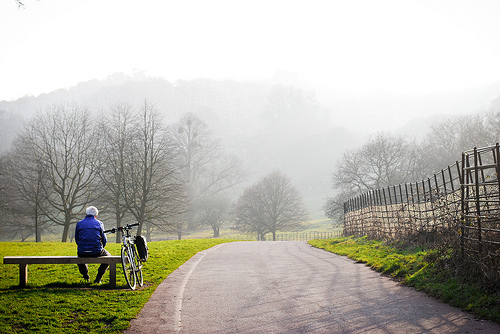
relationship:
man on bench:
[68, 202, 112, 283] [2, 254, 135, 288]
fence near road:
[244, 142, 498, 283] [138, 230, 494, 332]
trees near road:
[2, 108, 499, 240] [138, 230, 494, 332]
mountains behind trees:
[4, 90, 498, 242] [2, 108, 499, 240]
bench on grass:
[2, 254, 135, 288] [0, 240, 233, 333]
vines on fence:
[376, 194, 492, 273] [244, 142, 498, 283]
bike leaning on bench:
[102, 218, 150, 292] [2, 254, 135, 288]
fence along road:
[244, 142, 498, 283] [138, 230, 494, 332]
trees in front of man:
[2, 108, 499, 240] [68, 202, 112, 283]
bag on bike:
[131, 233, 154, 261] [102, 218, 150, 292]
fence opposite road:
[244, 142, 498, 283] [138, 230, 494, 332]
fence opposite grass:
[244, 142, 498, 283] [0, 240, 233, 333]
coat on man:
[68, 217, 111, 252] [68, 202, 112, 283]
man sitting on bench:
[68, 202, 112, 283] [2, 254, 135, 288]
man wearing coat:
[68, 202, 112, 283] [68, 217, 111, 252]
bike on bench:
[102, 218, 150, 292] [2, 254, 135, 288]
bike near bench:
[102, 218, 150, 292] [2, 254, 135, 288]